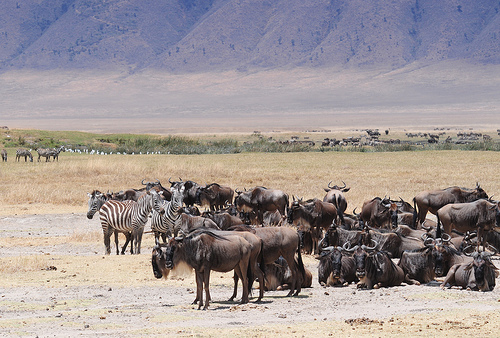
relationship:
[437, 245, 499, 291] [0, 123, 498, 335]
wildebeast in field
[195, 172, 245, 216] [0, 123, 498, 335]
wildebeast in field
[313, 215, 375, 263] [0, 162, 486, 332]
wildebeast in field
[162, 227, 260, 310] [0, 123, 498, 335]
wildebeest in field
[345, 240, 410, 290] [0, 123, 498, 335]
wildebeest in field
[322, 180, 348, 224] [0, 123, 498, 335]
wildebeest in field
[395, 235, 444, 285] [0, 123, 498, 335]
wildebeest in field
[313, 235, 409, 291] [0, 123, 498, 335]
wildebeest in field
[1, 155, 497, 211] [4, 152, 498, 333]
grass on ground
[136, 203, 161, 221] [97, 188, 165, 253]
stripes on body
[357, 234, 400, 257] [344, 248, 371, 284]
horns on head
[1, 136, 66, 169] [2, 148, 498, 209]
animals standing in grass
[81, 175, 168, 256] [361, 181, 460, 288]
zebras and wildbeests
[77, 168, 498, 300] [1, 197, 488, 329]
animals are standing in dirt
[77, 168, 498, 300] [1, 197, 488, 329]
animals are laying down in dirt